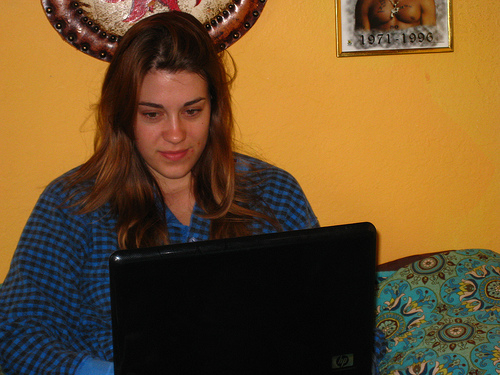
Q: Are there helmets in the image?
A: No, there are no helmets.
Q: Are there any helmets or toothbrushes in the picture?
A: No, there are no helmets or toothbrushes.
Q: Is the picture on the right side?
A: Yes, the picture is on the right of the image.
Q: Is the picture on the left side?
A: No, the picture is on the right of the image.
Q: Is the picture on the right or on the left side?
A: The picture is on the right of the image.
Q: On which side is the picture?
A: The picture is on the right of the image.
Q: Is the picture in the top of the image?
A: Yes, the picture is in the top of the image.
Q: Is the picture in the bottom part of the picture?
A: No, the picture is in the top of the image.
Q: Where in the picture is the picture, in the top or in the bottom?
A: The picture is in the top of the image.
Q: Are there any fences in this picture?
A: No, there are no fences.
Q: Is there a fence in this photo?
A: No, there are no fences.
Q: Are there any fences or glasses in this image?
A: No, there are no fences or glasses.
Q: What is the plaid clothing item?
A: The clothing item is a shirt.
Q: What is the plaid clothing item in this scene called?
A: The clothing item is a shirt.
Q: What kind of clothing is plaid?
A: The clothing is a shirt.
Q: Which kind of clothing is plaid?
A: The clothing is a shirt.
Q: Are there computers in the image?
A: Yes, there is a computer.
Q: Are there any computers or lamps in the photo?
A: Yes, there is a computer.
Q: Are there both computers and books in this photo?
A: No, there is a computer but no books.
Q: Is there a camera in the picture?
A: No, there are no cameras.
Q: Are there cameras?
A: No, there are no cameras.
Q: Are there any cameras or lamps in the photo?
A: No, there are no cameras or lamps.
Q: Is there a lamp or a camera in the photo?
A: No, there are no cameras or lamps.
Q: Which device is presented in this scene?
A: The device is a computer.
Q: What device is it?
A: The device is a computer.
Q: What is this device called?
A: That is a computer.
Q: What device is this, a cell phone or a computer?
A: That is a computer.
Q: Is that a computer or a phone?
A: That is a computer.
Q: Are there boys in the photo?
A: No, there are no boys.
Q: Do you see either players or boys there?
A: No, there are no boys or players.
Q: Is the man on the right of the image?
A: Yes, the man is on the right of the image.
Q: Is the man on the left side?
A: No, the man is on the right of the image.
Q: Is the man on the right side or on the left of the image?
A: The man is on the right of the image.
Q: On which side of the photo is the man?
A: The man is on the right of the image.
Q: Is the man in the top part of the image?
A: Yes, the man is in the top of the image.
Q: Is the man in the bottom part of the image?
A: No, the man is in the top of the image.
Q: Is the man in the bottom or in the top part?
A: The man is in the top of the image.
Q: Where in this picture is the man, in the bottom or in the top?
A: The man is in the top of the image.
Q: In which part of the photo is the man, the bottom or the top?
A: The man is in the top of the image.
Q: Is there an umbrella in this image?
A: No, there are no umbrellas.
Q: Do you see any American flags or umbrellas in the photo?
A: No, there are no umbrellas or American flags.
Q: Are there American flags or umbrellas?
A: No, there are no umbrellas or American flags.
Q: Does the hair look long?
A: Yes, the hair is long.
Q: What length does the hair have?
A: The hair has long length.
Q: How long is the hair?
A: The hair is long.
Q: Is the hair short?
A: No, the hair is long.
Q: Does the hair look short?
A: No, the hair is long.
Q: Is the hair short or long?
A: The hair is long.